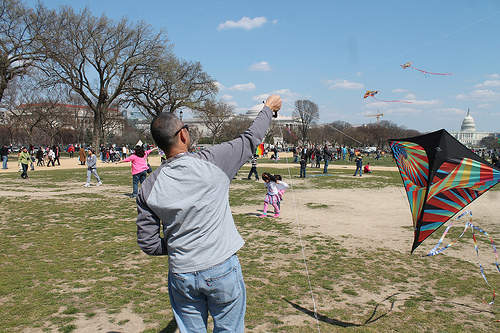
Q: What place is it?
A: It is a park.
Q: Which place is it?
A: It is a park.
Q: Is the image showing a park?
A: Yes, it is showing a park.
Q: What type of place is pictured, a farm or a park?
A: It is a park.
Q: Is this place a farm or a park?
A: It is a park.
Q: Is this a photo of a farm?
A: No, the picture is showing a park.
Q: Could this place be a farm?
A: No, it is a park.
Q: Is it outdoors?
A: Yes, it is outdoors.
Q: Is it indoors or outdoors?
A: It is outdoors.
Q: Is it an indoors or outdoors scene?
A: It is outdoors.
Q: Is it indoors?
A: No, it is outdoors.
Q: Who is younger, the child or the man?
A: The child is younger than the man.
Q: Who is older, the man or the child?
A: The man is older than the child.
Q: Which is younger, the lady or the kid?
A: The kid is younger than the lady.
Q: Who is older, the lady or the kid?
A: The lady is older than the kid.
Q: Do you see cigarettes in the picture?
A: No, there are no cigarettes.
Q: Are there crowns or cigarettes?
A: No, there are no cigarettes or crowns.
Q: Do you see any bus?
A: No, there are no buses.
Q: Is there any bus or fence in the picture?
A: No, there are no buses or fences.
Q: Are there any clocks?
A: No, there are no clocks.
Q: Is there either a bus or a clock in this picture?
A: No, there are no clocks or buses.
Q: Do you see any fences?
A: No, there are no fences.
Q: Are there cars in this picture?
A: No, there are no cars.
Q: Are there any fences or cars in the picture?
A: No, there are no cars or fences.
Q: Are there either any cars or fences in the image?
A: No, there are no cars or fences.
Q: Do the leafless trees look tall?
A: Yes, the trees are tall.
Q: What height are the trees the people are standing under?
A: The trees are tall.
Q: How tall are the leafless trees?
A: The trees are tall.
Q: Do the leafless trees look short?
A: No, the trees are tall.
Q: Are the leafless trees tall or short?
A: The trees are tall.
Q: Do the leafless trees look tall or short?
A: The trees are tall.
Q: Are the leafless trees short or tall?
A: The trees are tall.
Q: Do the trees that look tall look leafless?
A: Yes, the trees are leafless.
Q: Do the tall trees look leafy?
A: No, the trees are leafless.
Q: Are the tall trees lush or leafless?
A: The trees are leafless.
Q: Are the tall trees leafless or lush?
A: The trees are leafless.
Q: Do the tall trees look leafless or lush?
A: The trees are leafless.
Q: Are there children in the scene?
A: Yes, there is a child.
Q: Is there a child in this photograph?
A: Yes, there is a child.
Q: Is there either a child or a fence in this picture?
A: Yes, there is a child.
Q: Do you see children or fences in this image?
A: Yes, there is a child.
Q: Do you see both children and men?
A: Yes, there are both a child and a man.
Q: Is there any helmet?
A: No, there are no helmets.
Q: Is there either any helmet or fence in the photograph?
A: No, there are no helmets or fences.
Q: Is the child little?
A: Yes, the child is little.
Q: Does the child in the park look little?
A: Yes, the kid is little.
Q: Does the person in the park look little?
A: Yes, the kid is little.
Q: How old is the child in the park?
A: The kid is little.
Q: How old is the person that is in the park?
A: The kid is little.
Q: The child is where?
A: The child is in the park.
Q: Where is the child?
A: The child is in the park.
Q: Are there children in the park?
A: Yes, there is a child in the park.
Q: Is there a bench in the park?
A: No, there is a child in the park.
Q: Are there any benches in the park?
A: No, there is a child in the park.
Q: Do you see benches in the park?
A: No, there is a child in the park.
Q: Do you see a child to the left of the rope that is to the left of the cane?
A: Yes, there is a child to the left of the rope.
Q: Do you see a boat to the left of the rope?
A: No, there is a child to the left of the rope.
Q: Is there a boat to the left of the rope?
A: No, there is a child to the left of the rope.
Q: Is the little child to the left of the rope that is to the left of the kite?
A: Yes, the kid is to the left of the rope.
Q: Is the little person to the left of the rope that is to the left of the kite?
A: Yes, the kid is to the left of the rope.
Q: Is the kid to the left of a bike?
A: No, the kid is to the left of the rope.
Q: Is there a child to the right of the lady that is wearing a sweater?
A: Yes, there is a child to the right of the lady.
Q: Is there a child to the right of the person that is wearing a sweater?
A: Yes, there is a child to the right of the lady.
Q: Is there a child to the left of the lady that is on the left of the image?
A: No, the child is to the right of the lady.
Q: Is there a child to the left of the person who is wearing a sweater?
A: No, the child is to the right of the lady.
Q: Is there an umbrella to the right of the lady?
A: No, there is a child to the right of the lady.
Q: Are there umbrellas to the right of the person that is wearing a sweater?
A: No, there is a child to the right of the lady.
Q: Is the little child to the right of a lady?
A: Yes, the kid is to the right of a lady.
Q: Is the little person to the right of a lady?
A: Yes, the kid is to the right of a lady.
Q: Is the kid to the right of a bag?
A: No, the kid is to the right of a lady.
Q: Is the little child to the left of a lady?
A: No, the kid is to the right of a lady.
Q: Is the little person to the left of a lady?
A: No, the kid is to the right of a lady.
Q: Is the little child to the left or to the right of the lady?
A: The kid is to the right of the lady.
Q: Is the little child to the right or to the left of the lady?
A: The kid is to the right of the lady.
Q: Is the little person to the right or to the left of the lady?
A: The kid is to the right of the lady.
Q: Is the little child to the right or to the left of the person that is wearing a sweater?
A: The kid is to the right of the lady.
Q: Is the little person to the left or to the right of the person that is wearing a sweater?
A: The kid is to the right of the lady.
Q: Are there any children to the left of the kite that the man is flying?
A: Yes, there is a child to the left of the kite.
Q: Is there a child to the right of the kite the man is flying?
A: No, the child is to the left of the kite.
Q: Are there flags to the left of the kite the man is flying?
A: No, there is a child to the left of the kite.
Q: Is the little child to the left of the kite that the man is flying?
A: Yes, the kid is to the left of the kite.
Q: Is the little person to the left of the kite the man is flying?
A: Yes, the kid is to the left of the kite.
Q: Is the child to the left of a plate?
A: No, the child is to the left of the kite.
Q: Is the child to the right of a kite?
A: No, the child is to the left of a kite.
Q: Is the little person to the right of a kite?
A: No, the child is to the left of a kite.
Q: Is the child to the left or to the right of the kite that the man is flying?
A: The child is to the left of the kite.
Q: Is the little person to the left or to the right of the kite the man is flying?
A: The child is to the left of the kite.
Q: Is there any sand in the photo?
A: Yes, there is sand.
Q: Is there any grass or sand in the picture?
A: Yes, there is sand.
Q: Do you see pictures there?
A: No, there are no pictures.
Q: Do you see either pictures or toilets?
A: No, there are no pictures or toilets.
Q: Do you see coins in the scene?
A: No, there are no coins.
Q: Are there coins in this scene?
A: No, there are no coins.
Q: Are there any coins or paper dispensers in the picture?
A: No, there are no coins or paper dispensers.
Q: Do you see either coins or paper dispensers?
A: No, there are no coins or paper dispensers.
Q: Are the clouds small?
A: Yes, the clouds are small.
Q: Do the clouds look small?
A: Yes, the clouds are small.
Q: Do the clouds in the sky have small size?
A: Yes, the clouds are small.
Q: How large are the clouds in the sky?
A: The clouds are small.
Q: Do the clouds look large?
A: No, the clouds are small.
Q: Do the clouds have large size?
A: No, the clouds are small.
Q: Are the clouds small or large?
A: The clouds are small.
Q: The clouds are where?
A: The clouds are in the sky.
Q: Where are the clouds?
A: The clouds are in the sky.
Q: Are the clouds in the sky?
A: Yes, the clouds are in the sky.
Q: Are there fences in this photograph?
A: No, there are no fences.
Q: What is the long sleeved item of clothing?
A: The clothing item is a shirt.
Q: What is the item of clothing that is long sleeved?
A: The clothing item is a shirt.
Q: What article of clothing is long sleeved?
A: The clothing item is a shirt.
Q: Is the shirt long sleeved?
A: Yes, the shirt is long sleeved.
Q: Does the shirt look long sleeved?
A: Yes, the shirt is long sleeved.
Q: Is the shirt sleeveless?
A: No, the shirt is long sleeved.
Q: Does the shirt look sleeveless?
A: No, the shirt is long sleeved.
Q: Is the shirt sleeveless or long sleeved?
A: The shirt is long sleeved.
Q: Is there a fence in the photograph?
A: No, there are no fences.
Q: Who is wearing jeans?
A: The man is wearing jeans.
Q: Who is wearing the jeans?
A: The man is wearing jeans.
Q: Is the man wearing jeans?
A: Yes, the man is wearing jeans.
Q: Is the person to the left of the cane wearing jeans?
A: Yes, the man is wearing jeans.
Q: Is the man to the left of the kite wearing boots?
A: No, the man is wearing jeans.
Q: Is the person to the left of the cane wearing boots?
A: No, the man is wearing jeans.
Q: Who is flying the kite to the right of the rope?
A: The man is flying the kite.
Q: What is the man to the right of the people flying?
A: The man is flying the kite.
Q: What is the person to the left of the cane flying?
A: The man is flying the kite.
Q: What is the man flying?
A: The man is flying the kite.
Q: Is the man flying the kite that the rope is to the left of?
A: Yes, the man is flying the kite.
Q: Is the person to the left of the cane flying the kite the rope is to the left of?
A: Yes, the man is flying the kite.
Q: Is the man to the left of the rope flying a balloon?
A: No, the man is flying the kite.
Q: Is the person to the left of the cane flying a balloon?
A: No, the man is flying the kite.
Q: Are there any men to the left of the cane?
A: Yes, there is a man to the left of the cane.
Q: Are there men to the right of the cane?
A: No, the man is to the left of the cane.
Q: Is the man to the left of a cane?
A: Yes, the man is to the left of a cane.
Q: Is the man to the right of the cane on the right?
A: No, the man is to the left of the cane.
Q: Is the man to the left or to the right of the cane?
A: The man is to the left of the cane.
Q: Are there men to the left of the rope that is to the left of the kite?
A: Yes, there is a man to the left of the rope.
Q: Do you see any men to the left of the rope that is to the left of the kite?
A: Yes, there is a man to the left of the rope.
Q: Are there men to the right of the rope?
A: No, the man is to the left of the rope.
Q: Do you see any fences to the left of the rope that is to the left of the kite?
A: No, there is a man to the left of the rope.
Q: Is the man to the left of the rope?
A: Yes, the man is to the left of the rope.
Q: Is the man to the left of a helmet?
A: No, the man is to the left of the rope.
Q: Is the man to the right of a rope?
A: No, the man is to the left of a rope.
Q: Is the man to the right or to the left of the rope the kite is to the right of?
A: The man is to the left of the rope.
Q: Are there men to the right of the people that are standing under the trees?
A: Yes, there is a man to the right of the people.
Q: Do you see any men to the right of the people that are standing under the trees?
A: Yes, there is a man to the right of the people.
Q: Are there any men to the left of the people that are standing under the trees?
A: No, the man is to the right of the people.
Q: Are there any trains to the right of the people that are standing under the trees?
A: No, there is a man to the right of the people.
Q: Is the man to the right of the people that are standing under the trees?
A: Yes, the man is to the right of the people.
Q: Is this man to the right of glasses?
A: No, the man is to the right of the people.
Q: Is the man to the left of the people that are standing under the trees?
A: No, the man is to the right of the people.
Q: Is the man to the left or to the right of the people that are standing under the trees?
A: The man is to the right of the people.